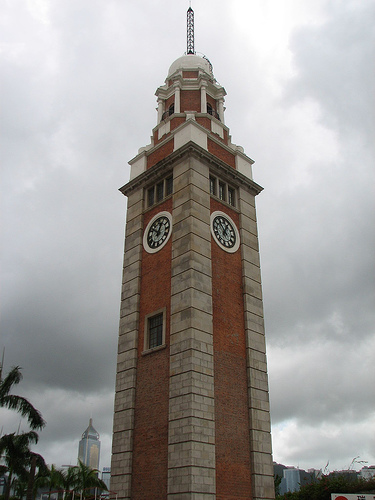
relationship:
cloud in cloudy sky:
[266, 334, 374, 424] [0, 0, 375, 475]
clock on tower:
[136, 208, 243, 255] [103, 0, 265, 317]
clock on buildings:
[208, 208, 244, 255] [108, 0, 275, 498]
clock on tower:
[142, 210, 240, 254] [99, 3, 288, 491]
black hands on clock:
[156, 218, 164, 234] [142, 210, 172, 253]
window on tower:
[143, 171, 176, 211] [99, 3, 288, 491]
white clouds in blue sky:
[277, 105, 327, 187] [263, 32, 356, 85]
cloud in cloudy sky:
[0, 0, 374, 470] [0, 0, 375, 475]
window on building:
[209, 168, 238, 213] [97, 0, 286, 498]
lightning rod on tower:
[185, 7, 196, 53] [99, 3, 288, 491]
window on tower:
[141, 307, 167, 356] [111, 22, 279, 493]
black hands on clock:
[150, 222, 163, 234] [141, 211, 173, 254]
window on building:
[141, 307, 167, 356] [112, 6, 272, 499]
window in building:
[205, 170, 244, 209] [106, 52, 279, 498]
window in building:
[139, 306, 168, 355] [123, 164, 255, 492]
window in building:
[142, 174, 173, 204] [106, 52, 279, 498]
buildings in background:
[40, 28, 367, 475] [2, 419, 363, 496]